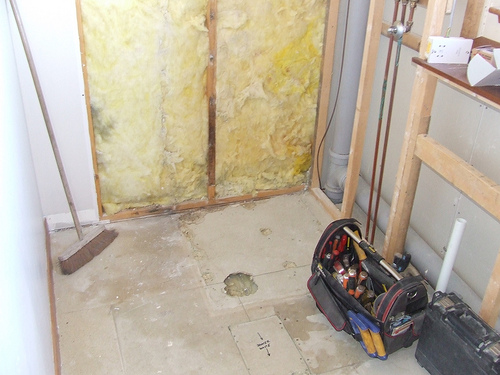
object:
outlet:
[428, 32, 478, 66]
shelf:
[408, 34, 499, 105]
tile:
[231, 313, 305, 374]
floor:
[48, 191, 434, 375]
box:
[308, 216, 429, 360]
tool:
[360, 265, 398, 292]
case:
[414, 289, 499, 373]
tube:
[362, 0, 403, 247]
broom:
[11, 0, 117, 272]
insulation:
[83, 3, 216, 214]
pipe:
[436, 211, 468, 293]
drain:
[223, 271, 259, 300]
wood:
[417, 133, 498, 215]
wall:
[305, 3, 499, 338]